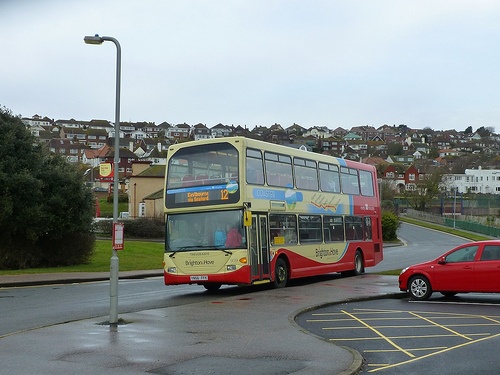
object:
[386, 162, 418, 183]
house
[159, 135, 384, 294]
bus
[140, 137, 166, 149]
house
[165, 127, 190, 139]
house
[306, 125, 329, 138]
house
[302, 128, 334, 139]
house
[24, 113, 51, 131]
house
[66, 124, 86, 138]
house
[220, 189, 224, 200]
number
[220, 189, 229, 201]
route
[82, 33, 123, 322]
pole lamp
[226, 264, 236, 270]
light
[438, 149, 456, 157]
house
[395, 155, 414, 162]
house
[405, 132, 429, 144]
house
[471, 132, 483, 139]
house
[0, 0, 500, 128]
sky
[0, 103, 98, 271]
bush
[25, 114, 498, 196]
hill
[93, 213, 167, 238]
hedges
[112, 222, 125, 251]
sign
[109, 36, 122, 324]
pole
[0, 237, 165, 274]
lawn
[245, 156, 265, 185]
window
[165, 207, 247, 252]
window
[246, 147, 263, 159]
window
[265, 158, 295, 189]
window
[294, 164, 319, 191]
window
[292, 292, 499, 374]
parking lot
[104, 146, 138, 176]
houses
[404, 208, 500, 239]
fence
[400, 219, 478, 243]
sidewalk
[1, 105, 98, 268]
tree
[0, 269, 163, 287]
sidewalk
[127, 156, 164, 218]
building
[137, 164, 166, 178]
roof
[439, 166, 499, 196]
building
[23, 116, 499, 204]
ridge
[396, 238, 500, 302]
car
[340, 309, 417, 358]
line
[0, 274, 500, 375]
pavement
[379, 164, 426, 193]
building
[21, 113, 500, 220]
city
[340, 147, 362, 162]
building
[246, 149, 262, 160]
glass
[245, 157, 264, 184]
glass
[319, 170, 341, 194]
glass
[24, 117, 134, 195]
hillside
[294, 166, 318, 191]
glass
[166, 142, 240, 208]
glass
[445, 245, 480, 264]
glass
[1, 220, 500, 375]
street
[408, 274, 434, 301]
tire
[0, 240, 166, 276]
grassy area